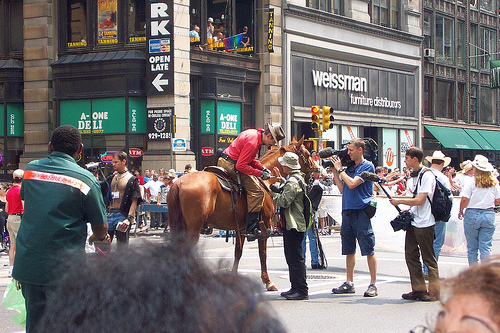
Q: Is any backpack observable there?
A: Yes, there is a backpack.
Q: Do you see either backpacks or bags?
A: Yes, there is a backpack.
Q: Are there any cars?
A: No, there are no cars.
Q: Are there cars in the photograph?
A: No, there are no cars.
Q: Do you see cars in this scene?
A: No, there are no cars.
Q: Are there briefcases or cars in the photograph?
A: No, there are no cars or briefcases.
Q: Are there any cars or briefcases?
A: No, there are no cars or briefcases.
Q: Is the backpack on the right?
A: Yes, the backpack is on the right of the image.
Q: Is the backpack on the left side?
A: No, the backpack is on the right of the image.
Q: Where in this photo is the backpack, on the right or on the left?
A: The backpack is on the right of the image.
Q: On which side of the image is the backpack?
A: The backpack is on the right of the image.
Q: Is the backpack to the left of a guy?
A: No, the backpack is to the right of a guy.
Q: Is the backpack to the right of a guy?
A: Yes, the backpack is to the right of a guy.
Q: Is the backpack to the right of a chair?
A: No, the backpack is to the right of a guy.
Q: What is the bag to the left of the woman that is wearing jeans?
A: The bag is a backpack.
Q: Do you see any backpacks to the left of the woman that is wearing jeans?
A: Yes, there is a backpack to the left of the woman.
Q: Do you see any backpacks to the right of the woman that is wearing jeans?
A: No, the backpack is to the left of the woman.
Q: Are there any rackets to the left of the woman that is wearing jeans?
A: No, there is a backpack to the left of the woman.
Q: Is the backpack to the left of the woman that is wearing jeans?
A: Yes, the backpack is to the left of the woman.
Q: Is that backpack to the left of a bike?
A: No, the backpack is to the left of the woman.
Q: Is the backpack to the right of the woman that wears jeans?
A: No, the backpack is to the left of the woman.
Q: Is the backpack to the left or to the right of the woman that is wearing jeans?
A: The backpack is to the left of the woman.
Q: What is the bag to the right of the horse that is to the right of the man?
A: The bag is a backpack.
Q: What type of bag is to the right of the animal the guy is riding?
A: The bag is a backpack.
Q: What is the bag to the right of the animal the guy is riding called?
A: The bag is a backpack.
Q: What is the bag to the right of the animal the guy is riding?
A: The bag is a backpack.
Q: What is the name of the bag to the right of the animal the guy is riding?
A: The bag is a backpack.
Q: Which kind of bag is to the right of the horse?
A: The bag is a backpack.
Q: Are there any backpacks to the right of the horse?
A: Yes, there is a backpack to the right of the horse.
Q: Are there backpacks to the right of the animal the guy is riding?
A: Yes, there is a backpack to the right of the horse.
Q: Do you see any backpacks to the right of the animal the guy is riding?
A: Yes, there is a backpack to the right of the horse.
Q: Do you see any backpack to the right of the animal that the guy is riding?
A: Yes, there is a backpack to the right of the horse.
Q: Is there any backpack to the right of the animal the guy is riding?
A: Yes, there is a backpack to the right of the horse.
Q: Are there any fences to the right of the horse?
A: No, there is a backpack to the right of the horse.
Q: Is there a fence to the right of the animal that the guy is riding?
A: No, there is a backpack to the right of the horse.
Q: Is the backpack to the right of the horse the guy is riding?
A: Yes, the backpack is to the right of the horse.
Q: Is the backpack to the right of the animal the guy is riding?
A: Yes, the backpack is to the right of the horse.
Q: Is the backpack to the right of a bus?
A: No, the backpack is to the right of the horse.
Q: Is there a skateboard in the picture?
A: No, there are no skateboards.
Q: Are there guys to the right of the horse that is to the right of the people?
A: Yes, there is a guy to the right of the horse.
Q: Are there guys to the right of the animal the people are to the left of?
A: Yes, there is a guy to the right of the horse.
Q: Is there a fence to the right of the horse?
A: No, there is a guy to the right of the horse.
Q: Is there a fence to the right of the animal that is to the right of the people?
A: No, there is a guy to the right of the horse.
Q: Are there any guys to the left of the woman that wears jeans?
A: Yes, there is a guy to the left of the woman.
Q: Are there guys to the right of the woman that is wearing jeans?
A: No, the guy is to the left of the woman.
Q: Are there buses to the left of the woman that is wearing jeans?
A: No, there is a guy to the left of the woman.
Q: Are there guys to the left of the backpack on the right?
A: Yes, there is a guy to the left of the backpack.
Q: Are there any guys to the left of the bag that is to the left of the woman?
A: Yes, there is a guy to the left of the backpack.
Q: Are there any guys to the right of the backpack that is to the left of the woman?
A: No, the guy is to the left of the backpack.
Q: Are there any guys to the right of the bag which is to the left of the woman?
A: No, the guy is to the left of the backpack.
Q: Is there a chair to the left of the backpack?
A: No, there is a guy to the left of the backpack.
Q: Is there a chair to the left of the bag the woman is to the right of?
A: No, there is a guy to the left of the backpack.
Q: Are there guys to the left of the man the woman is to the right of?
A: Yes, there is a guy to the left of the man.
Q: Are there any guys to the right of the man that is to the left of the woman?
A: No, the guy is to the left of the man.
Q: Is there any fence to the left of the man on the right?
A: No, there is a guy to the left of the man.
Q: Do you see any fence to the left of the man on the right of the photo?
A: No, there is a guy to the left of the man.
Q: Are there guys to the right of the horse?
A: Yes, there is a guy to the right of the horse.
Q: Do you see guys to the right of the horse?
A: Yes, there is a guy to the right of the horse.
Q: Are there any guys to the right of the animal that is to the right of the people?
A: Yes, there is a guy to the right of the horse.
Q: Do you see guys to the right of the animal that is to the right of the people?
A: Yes, there is a guy to the right of the horse.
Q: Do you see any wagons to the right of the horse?
A: No, there is a guy to the right of the horse.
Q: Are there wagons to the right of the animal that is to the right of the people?
A: No, there is a guy to the right of the horse.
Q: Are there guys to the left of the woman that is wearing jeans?
A: Yes, there is a guy to the left of the woman.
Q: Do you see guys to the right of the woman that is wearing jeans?
A: No, the guy is to the left of the woman.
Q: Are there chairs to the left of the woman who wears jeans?
A: No, there is a guy to the left of the woman.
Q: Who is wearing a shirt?
A: The guy is wearing a shirt.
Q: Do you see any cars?
A: No, there are no cars.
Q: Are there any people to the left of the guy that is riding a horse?
A: Yes, there are people to the left of the guy.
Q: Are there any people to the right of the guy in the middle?
A: No, the people are to the left of the guy.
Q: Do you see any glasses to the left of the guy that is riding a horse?
A: No, there are people to the left of the guy.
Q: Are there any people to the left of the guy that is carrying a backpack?
A: Yes, there are people to the left of the guy.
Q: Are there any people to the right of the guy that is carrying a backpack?
A: No, the people are to the left of the guy.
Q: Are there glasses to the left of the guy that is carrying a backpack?
A: No, there are people to the left of the guy.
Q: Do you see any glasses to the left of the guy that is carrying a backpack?
A: No, there are people to the left of the guy.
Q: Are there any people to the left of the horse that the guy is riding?
A: Yes, there are people to the left of the horse.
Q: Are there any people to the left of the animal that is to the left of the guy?
A: Yes, there are people to the left of the horse.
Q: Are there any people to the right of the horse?
A: No, the people are to the left of the horse.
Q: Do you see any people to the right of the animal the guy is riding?
A: No, the people are to the left of the horse.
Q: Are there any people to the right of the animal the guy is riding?
A: No, the people are to the left of the horse.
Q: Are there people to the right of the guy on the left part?
A: Yes, there are people to the right of the guy.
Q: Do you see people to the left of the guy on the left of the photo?
A: No, the people are to the right of the guy.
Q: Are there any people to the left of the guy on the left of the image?
A: No, the people are to the right of the guy.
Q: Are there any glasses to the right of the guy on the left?
A: No, there are people to the right of the guy.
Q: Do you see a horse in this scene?
A: Yes, there is a horse.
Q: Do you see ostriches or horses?
A: Yes, there is a horse.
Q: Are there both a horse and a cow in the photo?
A: No, there is a horse but no cows.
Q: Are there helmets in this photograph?
A: No, there are no helmets.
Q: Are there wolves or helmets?
A: No, there are no helmets or wolves.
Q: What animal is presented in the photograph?
A: The animal is a horse.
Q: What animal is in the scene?
A: The animal is a horse.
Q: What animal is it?
A: The animal is a horse.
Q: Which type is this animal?
A: This is a horse.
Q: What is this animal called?
A: This is a horse.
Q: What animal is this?
A: This is a horse.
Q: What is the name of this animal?
A: This is a horse.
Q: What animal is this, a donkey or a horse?
A: This is a horse.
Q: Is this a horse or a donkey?
A: This is a horse.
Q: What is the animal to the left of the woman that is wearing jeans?
A: The animal is a horse.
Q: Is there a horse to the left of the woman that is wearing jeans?
A: Yes, there is a horse to the left of the woman.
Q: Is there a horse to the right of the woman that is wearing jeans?
A: No, the horse is to the left of the woman.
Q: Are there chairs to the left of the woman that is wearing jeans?
A: No, there is a horse to the left of the woman.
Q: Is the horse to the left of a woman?
A: Yes, the horse is to the left of a woman.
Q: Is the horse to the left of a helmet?
A: No, the horse is to the left of a woman.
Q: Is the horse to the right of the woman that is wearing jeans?
A: No, the horse is to the left of the woman.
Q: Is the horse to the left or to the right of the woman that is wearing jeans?
A: The horse is to the left of the woman.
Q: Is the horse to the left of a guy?
A: Yes, the horse is to the left of a guy.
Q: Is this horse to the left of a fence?
A: No, the horse is to the left of a guy.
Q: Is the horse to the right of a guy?
A: No, the horse is to the left of a guy.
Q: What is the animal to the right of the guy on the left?
A: The animal is a horse.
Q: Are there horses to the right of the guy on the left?
A: Yes, there is a horse to the right of the guy.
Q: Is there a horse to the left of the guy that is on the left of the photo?
A: No, the horse is to the right of the guy.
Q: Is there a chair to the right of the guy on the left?
A: No, there is a horse to the right of the guy.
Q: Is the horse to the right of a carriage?
A: No, the horse is to the right of a guy.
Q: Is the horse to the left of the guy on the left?
A: No, the horse is to the right of the guy.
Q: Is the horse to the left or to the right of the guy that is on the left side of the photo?
A: The horse is to the right of the guy.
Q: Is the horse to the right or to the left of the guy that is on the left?
A: The horse is to the right of the guy.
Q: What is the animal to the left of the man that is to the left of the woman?
A: The animal is a horse.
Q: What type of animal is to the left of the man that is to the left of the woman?
A: The animal is a horse.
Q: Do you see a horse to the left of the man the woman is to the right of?
A: Yes, there is a horse to the left of the man.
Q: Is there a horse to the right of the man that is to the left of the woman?
A: No, the horse is to the left of the man.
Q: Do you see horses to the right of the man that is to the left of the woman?
A: No, the horse is to the left of the man.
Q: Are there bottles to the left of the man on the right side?
A: No, there is a horse to the left of the man.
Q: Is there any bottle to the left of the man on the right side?
A: No, there is a horse to the left of the man.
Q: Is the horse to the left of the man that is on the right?
A: Yes, the horse is to the left of the man.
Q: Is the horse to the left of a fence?
A: No, the horse is to the left of the man.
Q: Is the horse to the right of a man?
A: No, the horse is to the left of a man.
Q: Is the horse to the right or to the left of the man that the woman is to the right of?
A: The horse is to the left of the man.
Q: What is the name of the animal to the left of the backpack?
A: The animal is a horse.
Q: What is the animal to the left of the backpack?
A: The animal is a horse.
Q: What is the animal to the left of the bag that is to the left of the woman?
A: The animal is a horse.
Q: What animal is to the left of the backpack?
A: The animal is a horse.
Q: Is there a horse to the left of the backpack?
A: Yes, there is a horse to the left of the backpack.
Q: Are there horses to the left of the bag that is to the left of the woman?
A: Yes, there is a horse to the left of the backpack.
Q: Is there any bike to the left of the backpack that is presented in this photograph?
A: No, there is a horse to the left of the backpack.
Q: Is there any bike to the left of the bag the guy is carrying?
A: No, there is a horse to the left of the backpack.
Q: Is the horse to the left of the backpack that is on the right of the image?
A: Yes, the horse is to the left of the backpack.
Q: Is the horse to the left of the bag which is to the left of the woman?
A: Yes, the horse is to the left of the backpack.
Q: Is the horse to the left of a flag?
A: No, the horse is to the left of the backpack.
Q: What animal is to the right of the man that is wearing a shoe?
A: The animal is a horse.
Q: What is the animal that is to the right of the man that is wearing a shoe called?
A: The animal is a horse.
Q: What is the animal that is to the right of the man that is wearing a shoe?
A: The animal is a horse.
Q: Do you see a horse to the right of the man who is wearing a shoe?
A: Yes, there is a horse to the right of the man.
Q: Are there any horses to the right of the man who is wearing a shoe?
A: Yes, there is a horse to the right of the man.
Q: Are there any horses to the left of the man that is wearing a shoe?
A: No, the horse is to the right of the man.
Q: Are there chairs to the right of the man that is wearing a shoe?
A: No, there is a horse to the right of the man.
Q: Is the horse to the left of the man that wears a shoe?
A: No, the horse is to the right of the man.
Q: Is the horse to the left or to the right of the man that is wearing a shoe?
A: The horse is to the right of the man.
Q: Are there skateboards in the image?
A: No, there are no skateboards.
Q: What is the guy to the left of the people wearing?
A: The guy is wearing a shirt.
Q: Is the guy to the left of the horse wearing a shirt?
A: Yes, the guy is wearing a shirt.